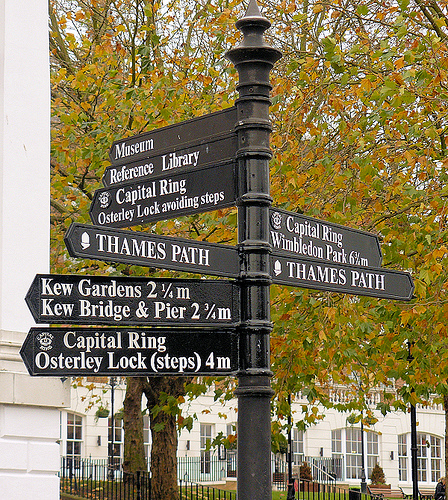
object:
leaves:
[327, 88, 375, 162]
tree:
[283, 12, 447, 192]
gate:
[61, 458, 121, 498]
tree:
[51, 0, 189, 499]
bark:
[148, 376, 178, 499]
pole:
[224, 0, 285, 499]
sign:
[261, 206, 383, 267]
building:
[64, 373, 447, 490]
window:
[65, 411, 81, 469]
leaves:
[76, 480, 112, 498]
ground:
[79, 485, 369, 500]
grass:
[185, 480, 233, 492]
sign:
[63, 221, 237, 278]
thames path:
[271, 252, 416, 302]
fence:
[278, 484, 362, 500]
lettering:
[146, 138, 155, 151]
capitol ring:
[286, 215, 352, 249]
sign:
[100, 127, 237, 188]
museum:
[114, 138, 154, 159]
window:
[331, 427, 378, 479]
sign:
[17, 326, 238, 376]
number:
[205, 352, 215, 370]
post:
[286, 397, 295, 499]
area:
[178, 481, 352, 499]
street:
[63, 483, 448, 496]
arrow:
[108, 106, 237, 165]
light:
[381, 445, 395, 463]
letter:
[96, 178, 224, 226]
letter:
[270, 231, 369, 267]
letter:
[40, 276, 191, 300]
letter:
[94, 232, 209, 266]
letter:
[285, 214, 343, 249]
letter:
[113, 139, 153, 161]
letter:
[171, 244, 211, 267]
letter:
[34, 351, 230, 370]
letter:
[40, 298, 232, 324]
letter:
[77, 299, 231, 322]